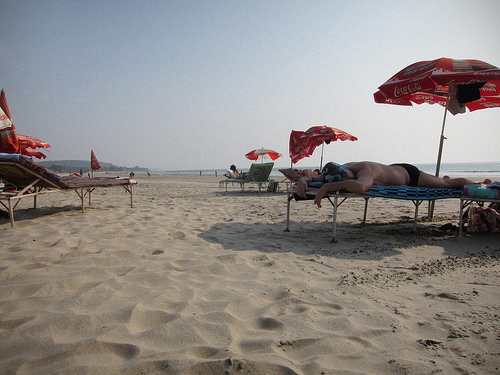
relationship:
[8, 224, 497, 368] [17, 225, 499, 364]
bunch of sand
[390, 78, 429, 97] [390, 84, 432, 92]
logo for coca-cola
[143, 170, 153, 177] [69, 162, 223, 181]
beach goer in distance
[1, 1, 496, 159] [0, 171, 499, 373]
sky above ground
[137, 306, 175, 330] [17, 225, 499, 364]
print in sand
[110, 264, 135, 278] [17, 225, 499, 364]
print in sand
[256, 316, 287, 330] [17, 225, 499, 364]
print in sand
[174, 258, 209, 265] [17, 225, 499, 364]
print in sand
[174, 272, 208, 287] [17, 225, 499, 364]
print in sand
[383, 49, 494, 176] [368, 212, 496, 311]
umbrella above ground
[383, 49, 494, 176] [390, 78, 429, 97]
umbrella has logo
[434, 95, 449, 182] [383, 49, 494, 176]
pole on umbrella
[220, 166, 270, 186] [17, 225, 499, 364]
recliner on sand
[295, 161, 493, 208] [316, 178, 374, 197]
man has arm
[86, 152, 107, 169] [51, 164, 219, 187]
umbrella in background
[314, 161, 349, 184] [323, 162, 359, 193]
hat on head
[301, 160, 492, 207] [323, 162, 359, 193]
man has head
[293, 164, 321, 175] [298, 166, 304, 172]
woman has cell phone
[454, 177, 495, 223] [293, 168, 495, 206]
table next to beach chair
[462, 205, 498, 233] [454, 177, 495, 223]
bag under table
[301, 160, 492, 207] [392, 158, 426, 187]
man wearing bathing suit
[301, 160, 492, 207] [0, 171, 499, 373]
man at beach